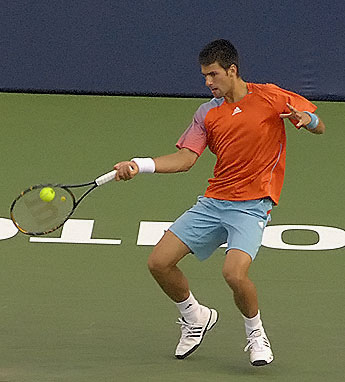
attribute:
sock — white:
[237, 308, 265, 337]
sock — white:
[172, 286, 202, 326]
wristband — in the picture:
[129, 155, 157, 177]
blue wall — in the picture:
[242, 5, 335, 79]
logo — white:
[231, 105, 242, 118]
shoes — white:
[169, 305, 221, 359]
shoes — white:
[233, 314, 278, 366]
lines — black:
[182, 331, 203, 338]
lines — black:
[184, 327, 204, 333]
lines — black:
[187, 322, 204, 329]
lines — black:
[261, 342, 272, 349]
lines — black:
[262, 334, 269, 346]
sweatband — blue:
[301, 105, 318, 130]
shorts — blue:
[168, 195, 272, 262]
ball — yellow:
[31, 182, 61, 201]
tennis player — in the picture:
[111, 36, 324, 371]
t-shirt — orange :
[201, 102, 269, 189]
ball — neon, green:
[34, 184, 57, 203]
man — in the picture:
[110, 35, 327, 370]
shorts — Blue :
[140, 172, 290, 273]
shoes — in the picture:
[159, 300, 279, 354]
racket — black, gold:
[8, 171, 115, 235]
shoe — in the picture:
[174, 303, 217, 358]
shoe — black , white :
[243, 324, 274, 369]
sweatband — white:
[129, 156, 156, 174]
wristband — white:
[131, 154, 156, 172]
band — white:
[130, 148, 156, 188]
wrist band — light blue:
[296, 109, 321, 137]